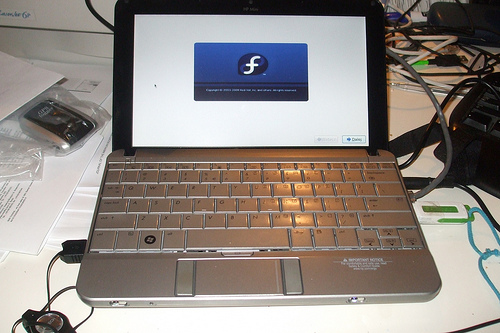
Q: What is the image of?
A: A laptop.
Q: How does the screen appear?
A: On.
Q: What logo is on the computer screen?
A: Facebook.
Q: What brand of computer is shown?
A: Windows.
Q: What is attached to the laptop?
A: USB port.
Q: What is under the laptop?
A: A bunch of papers.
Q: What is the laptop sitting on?
A: Table.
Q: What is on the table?
A: Laptop.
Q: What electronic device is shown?
A: Laptop.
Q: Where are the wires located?
A: Behind the laptop.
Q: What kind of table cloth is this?
A: This is a white tablecloth.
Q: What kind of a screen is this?
A: This is a white screen.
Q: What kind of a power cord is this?
A: This is a black power cord.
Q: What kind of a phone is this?
A: This is a silver and black phone.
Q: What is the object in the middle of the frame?
A: Laptop computer.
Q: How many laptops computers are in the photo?
A: One.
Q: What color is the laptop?
A: Silver and black.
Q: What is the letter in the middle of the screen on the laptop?
A: F.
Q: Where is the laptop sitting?
A: Table.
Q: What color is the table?
A: White.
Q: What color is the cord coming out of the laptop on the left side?
A: Black.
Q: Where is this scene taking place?
A: In front of computer.